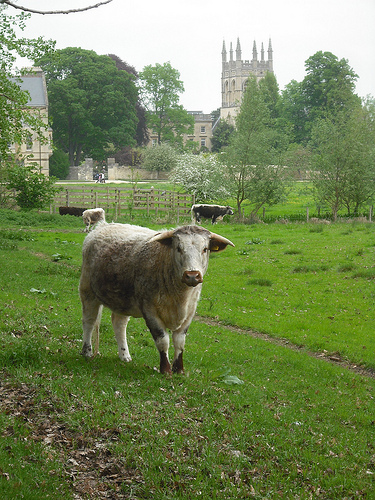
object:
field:
[0, 179, 375, 499]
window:
[201, 125, 207, 135]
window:
[199, 139, 207, 152]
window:
[190, 136, 194, 142]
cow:
[81, 206, 235, 374]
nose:
[182, 267, 203, 282]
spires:
[235, 35, 243, 61]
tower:
[221, 39, 275, 130]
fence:
[0, 183, 194, 222]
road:
[0, 178, 148, 185]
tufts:
[0, 36, 340, 218]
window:
[26, 136, 36, 151]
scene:
[0, 0, 375, 499]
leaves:
[42, 418, 53, 430]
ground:
[0, 178, 375, 498]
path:
[192, 315, 375, 377]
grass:
[0, 209, 375, 499]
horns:
[142, 225, 183, 248]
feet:
[156, 356, 173, 377]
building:
[144, 112, 211, 160]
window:
[229, 79, 236, 86]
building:
[0, 66, 55, 184]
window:
[223, 79, 229, 85]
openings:
[224, 80, 230, 91]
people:
[94, 168, 106, 182]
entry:
[91, 160, 110, 180]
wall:
[108, 156, 170, 180]